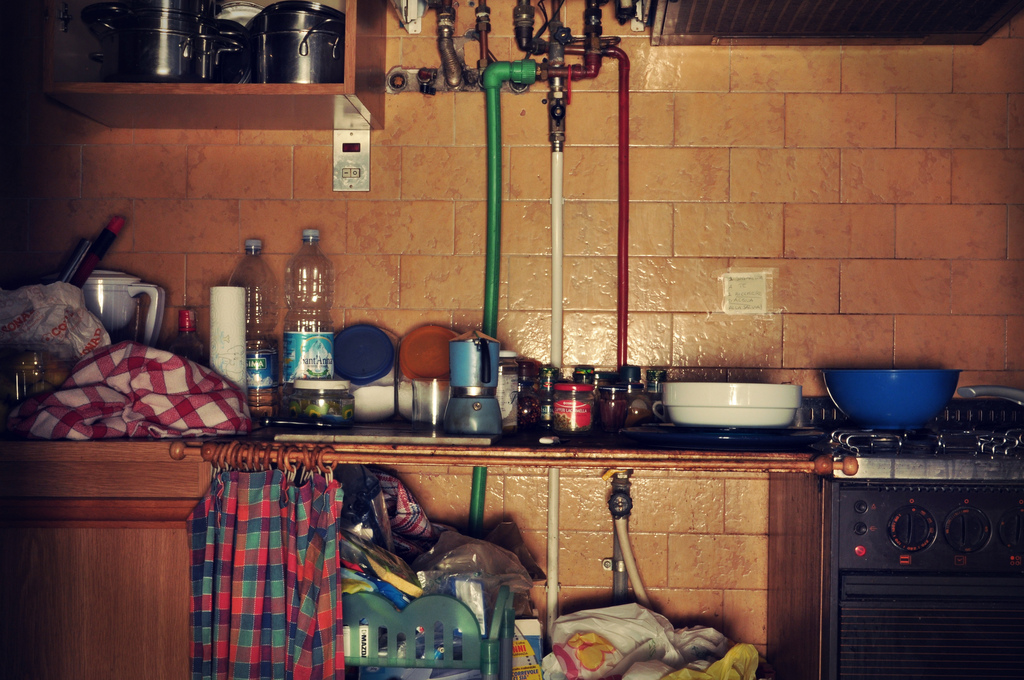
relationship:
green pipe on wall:
[472, 61, 524, 330] [703, 76, 1019, 327]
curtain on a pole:
[187, 436, 343, 678] [154, 435, 865, 483]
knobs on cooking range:
[843, 496, 1021, 563] [806, 402, 1018, 677]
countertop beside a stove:
[17, 395, 839, 517] [780, 421, 1014, 677]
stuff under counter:
[322, 477, 731, 678] [203, 429, 876, 507]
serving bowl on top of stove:
[832, 358, 958, 439] [754, 399, 996, 678]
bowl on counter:
[661, 373, 806, 432] [225, 429, 828, 477]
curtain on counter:
[188, 436, 344, 678] [236, 440, 842, 480]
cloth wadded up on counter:
[17, 354, 259, 439] [9, 429, 828, 503]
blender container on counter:
[87, 265, 176, 365] [9, 429, 828, 503]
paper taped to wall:
[709, 272, 787, 324] [9, 12, 1006, 402]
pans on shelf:
[20, 0, 332, 74] [2, 64, 340, 127]